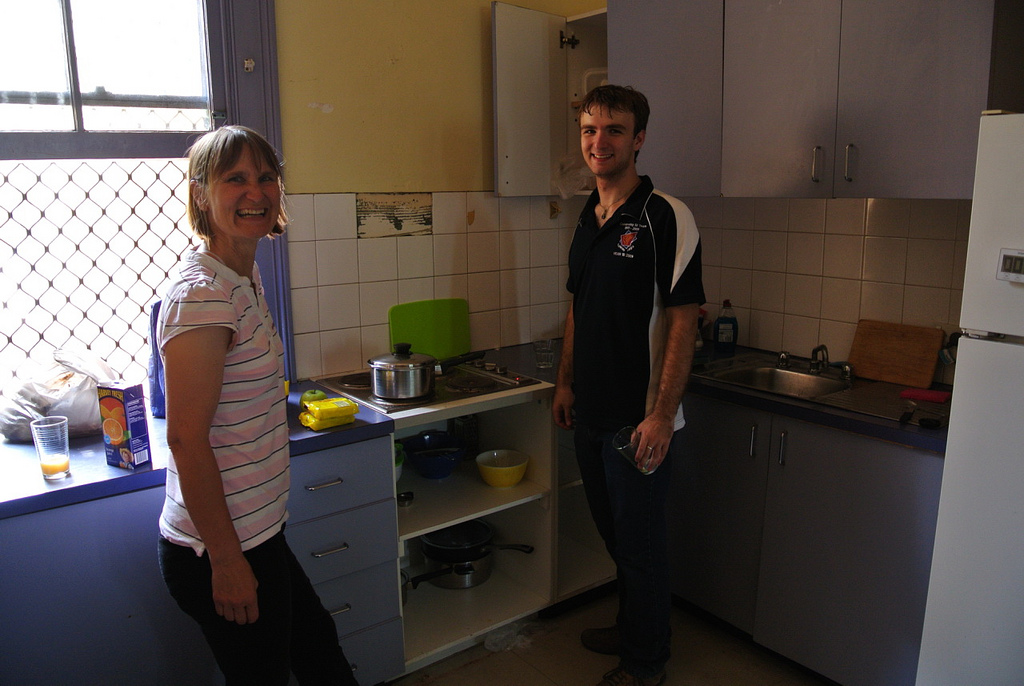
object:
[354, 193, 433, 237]
bare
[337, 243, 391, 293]
tiles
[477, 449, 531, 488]
mixing bowl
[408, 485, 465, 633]
shelf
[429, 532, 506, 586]
pans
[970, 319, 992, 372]
wall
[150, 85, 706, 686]
two people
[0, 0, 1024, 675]
kitchen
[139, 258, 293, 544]
shirt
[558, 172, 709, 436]
shirt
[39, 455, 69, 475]
juice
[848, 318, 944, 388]
board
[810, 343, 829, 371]
faucet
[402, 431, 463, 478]
pot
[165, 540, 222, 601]
white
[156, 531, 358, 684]
black pants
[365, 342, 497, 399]
black burner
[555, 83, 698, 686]
man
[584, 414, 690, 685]
jeans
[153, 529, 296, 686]
pants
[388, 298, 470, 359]
board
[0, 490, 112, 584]
top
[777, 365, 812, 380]
liquid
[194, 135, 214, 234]
hair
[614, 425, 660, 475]
glass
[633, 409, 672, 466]
hand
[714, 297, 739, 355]
bottle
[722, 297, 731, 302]
cap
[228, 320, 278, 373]
lines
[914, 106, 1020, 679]
refrigerator